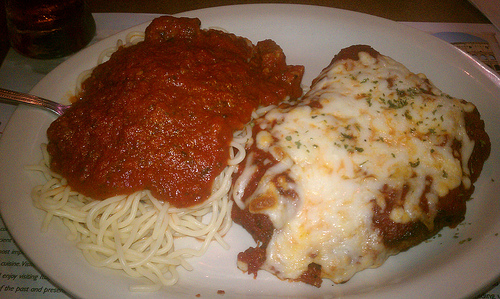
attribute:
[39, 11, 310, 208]
sauce — red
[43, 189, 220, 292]
pasta — white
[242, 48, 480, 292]
cheese — melted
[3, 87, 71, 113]
fork — silver, metal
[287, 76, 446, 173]
herb — green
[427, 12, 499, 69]
tablecloth — white,  blue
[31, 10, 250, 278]
noodles — yummy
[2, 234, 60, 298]
newsprint — black, white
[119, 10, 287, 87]
food — sauce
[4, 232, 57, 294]
paper — white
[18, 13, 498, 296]
plate — white